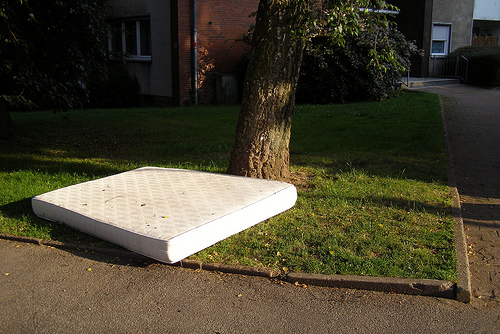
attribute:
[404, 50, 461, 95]
puddle — of water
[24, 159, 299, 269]
mattress — white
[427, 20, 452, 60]
white window — white framed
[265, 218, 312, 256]
grass — green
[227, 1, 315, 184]
bark — of tree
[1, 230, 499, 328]
road — asphalt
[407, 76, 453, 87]
step — small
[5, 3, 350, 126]
building — brick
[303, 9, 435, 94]
bush — large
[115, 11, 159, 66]
window — dark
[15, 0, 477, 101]
building — brick, apartment building